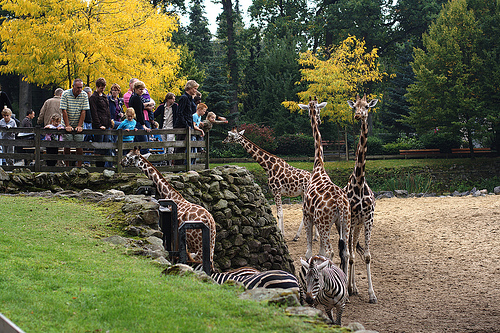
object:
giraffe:
[121, 145, 217, 263]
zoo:
[1, 0, 499, 332]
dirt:
[267, 193, 499, 331]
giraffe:
[295, 254, 350, 327]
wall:
[140, 166, 295, 276]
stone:
[223, 187, 237, 201]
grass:
[2, 195, 347, 331]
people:
[1, 107, 19, 166]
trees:
[1, 1, 191, 108]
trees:
[281, 33, 397, 161]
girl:
[202, 112, 228, 135]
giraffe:
[221, 125, 319, 242]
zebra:
[205, 268, 300, 298]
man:
[193, 103, 211, 136]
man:
[89, 79, 117, 167]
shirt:
[89, 90, 114, 130]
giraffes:
[296, 96, 354, 303]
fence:
[1, 126, 211, 172]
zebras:
[296, 255, 346, 327]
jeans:
[92, 126, 113, 167]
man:
[129, 82, 151, 155]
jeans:
[134, 124, 150, 155]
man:
[176, 79, 201, 166]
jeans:
[175, 132, 187, 167]